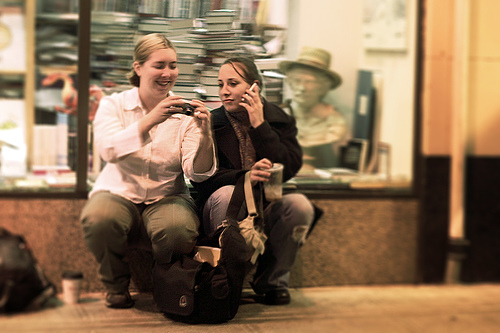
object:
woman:
[201, 57, 316, 310]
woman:
[75, 29, 221, 309]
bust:
[274, 48, 355, 165]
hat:
[270, 47, 343, 83]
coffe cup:
[54, 270, 93, 306]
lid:
[60, 271, 85, 280]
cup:
[259, 162, 287, 203]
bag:
[156, 216, 249, 327]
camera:
[176, 102, 198, 118]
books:
[160, 5, 249, 32]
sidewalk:
[1, 284, 499, 333]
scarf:
[220, 108, 258, 172]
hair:
[126, 31, 178, 86]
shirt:
[87, 85, 219, 205]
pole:
[441, 2, 475, 284]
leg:
[253, 192, 323, 288]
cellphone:
[240, 82, 262, 103]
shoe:
[248, 277, 293, 306]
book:
[165, 20, 200, 32]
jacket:
[189, 105, 306, 205]